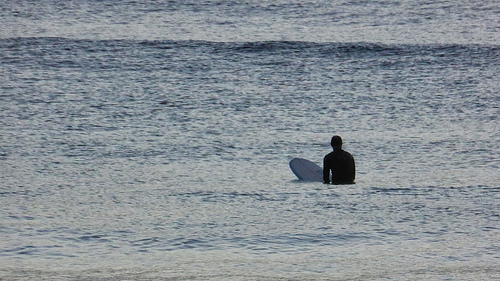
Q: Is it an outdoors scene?
A: Yes, it is outdoors.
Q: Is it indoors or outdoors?
A: It is outdoors.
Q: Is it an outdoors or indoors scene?
A: It is outdoors.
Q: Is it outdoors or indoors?
A: It is outdoors.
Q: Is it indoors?
A: No, it is outdoors.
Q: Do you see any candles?
A: No, there are no candles.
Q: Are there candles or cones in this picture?
A: No, there are no candles or cones.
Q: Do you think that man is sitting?
A: Yes, the man is sitting.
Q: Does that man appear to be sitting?
A: Yes, the man is sitting.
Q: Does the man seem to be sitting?
A: Yes, the man is sitting.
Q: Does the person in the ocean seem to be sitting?
A: Yes, the man is sitting.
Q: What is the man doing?
A: The man is sitting.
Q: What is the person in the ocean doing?
A: The man is sitting.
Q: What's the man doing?
A: The man is sitting.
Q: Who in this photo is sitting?
A: The man is sitting.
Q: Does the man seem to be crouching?
A: No, the man is sitting.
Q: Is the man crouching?
A: No, the man is sitting.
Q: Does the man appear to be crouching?
A: No, the man is sitting.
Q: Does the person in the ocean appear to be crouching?
A: No, the man is sitting.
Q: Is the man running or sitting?
A: The man is sitting.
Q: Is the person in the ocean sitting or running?
A: The man is sitting.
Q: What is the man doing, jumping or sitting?
A: The man is sitting.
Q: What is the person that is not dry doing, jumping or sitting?
A: The man is sitting.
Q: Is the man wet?
A: Yes, the man is wet.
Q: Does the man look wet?
A: Yes, the man is wet.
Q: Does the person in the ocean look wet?
A: Yes, the man is wet.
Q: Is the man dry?
A: No, the man is wet.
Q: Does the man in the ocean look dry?
A: No, the man is wet.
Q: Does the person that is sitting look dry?
A: No, the man is wet.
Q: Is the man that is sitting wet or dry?
A: The man is wet.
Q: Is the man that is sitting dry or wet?
A: The man is wet.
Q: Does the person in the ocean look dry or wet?
A: The man is wet.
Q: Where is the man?
A: The man is in the ocean.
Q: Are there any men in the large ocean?
A: Yes, there is a man in the ocean.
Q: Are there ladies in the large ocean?
A: No, there is a man in the ocean.